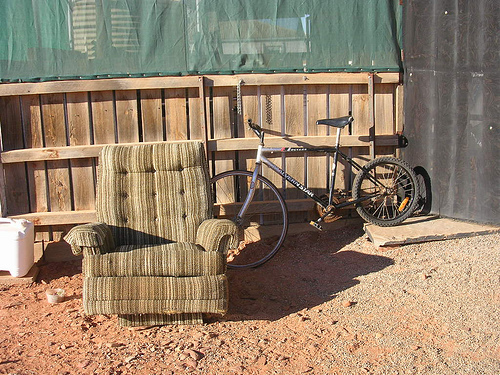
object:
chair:
[64, 138, 236, 323]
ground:
[0, 258, 499, 373]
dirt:
[316, 291, 456, 361]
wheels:
[350, 155, 423, 229]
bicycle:
[211, 111, 429, 270]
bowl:
[43, 284, 71, 304]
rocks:
[129, 338, 166, 361]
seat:
[312, 112, 359, 128]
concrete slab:
[361, 225, 490, 245]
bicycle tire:
[352, 154, 423, 228]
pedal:
[306, 216, 340, 240]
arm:
[193, 221, 244, 250]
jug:
[1, 216, 37, 278]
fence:
[0, 75, 439, 241]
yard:
[3, 5, 489, 373]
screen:
[3, 2, 398, 67]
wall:
[4, 86, 403, 193]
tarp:
[404, 7, 499, 222]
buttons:
[175, 207, 193, 222]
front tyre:
[216, 165, 291, 273]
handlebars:
[238, 115, 269, 134]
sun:
[95, 150, 231, 240]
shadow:
[212, 230, 395, 323]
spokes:
[217, 188, 275, 221]